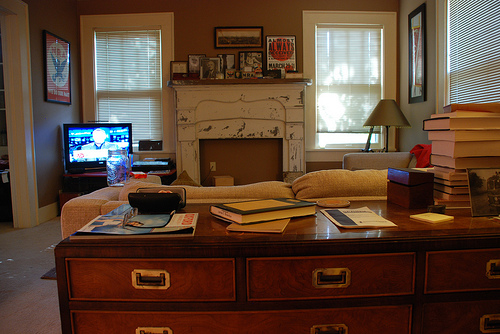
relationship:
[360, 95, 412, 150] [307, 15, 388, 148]
lamp sitting by window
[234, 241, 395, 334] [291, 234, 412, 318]
part of a drawer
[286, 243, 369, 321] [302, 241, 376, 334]
part of a handle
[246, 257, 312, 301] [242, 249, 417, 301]
part of a drawer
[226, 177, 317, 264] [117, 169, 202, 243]
edge of a book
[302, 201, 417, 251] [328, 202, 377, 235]
part of a paper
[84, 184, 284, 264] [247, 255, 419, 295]
part of a board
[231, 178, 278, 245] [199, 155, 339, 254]
part of a book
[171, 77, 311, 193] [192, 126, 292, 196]
fireplace with no fire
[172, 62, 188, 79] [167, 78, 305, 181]
photos on fireplace mantle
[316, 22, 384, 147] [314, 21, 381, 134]
window with large white frame and blinds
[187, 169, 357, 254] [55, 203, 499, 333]
pile of books on chest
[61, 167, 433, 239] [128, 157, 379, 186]
couch behind table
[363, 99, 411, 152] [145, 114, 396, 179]
lamp behind couch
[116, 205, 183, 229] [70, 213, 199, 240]
glasses on book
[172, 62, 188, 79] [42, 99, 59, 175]
photos on wall with thin black frame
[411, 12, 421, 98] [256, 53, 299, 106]
painting on wall with thin black frame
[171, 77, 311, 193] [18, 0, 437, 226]
fireplace in wall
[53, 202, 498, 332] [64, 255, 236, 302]
chest of drawer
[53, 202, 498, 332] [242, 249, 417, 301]
chest of drawer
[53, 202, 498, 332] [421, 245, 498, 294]
chest of drawer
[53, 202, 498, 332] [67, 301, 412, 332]
chest of drawer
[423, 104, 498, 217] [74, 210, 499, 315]
books are stacked on chest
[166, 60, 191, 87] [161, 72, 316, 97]
photos on mantel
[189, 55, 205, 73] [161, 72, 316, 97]
photograph on mantel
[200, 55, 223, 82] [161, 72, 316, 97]
photos on mantel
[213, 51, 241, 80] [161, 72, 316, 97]
photos on mantel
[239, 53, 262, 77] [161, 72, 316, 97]
photograph on mantel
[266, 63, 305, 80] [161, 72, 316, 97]
knickknacks on mantel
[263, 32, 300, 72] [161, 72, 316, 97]
knickknacks on mantel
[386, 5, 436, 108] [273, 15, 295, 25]
painting on wall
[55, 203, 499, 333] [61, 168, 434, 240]
chest behind couch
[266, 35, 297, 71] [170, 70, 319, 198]
frame on mantle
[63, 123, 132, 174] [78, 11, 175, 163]
black tv near window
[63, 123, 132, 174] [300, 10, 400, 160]
black tv near window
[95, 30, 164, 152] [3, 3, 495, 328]
window in living room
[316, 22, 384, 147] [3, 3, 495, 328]
window in living room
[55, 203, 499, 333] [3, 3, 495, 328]
chest in living room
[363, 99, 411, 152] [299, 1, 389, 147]
lamp near window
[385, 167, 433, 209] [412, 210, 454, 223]
box holds cards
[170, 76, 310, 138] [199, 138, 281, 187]
mantle over fireplace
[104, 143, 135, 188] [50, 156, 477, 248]
mason jar on couch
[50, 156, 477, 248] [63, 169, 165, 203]
couch has arm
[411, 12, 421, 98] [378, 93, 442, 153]
painting on wall